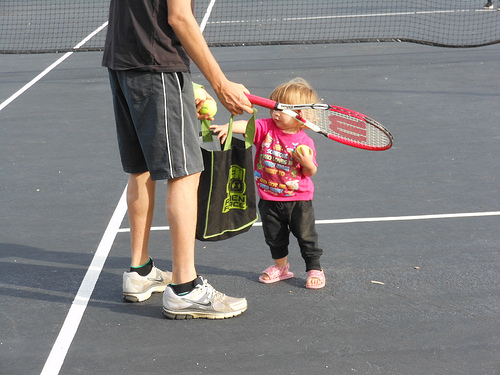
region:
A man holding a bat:
[210, 46, 402, 161]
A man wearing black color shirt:
[90, 0, 210, 150]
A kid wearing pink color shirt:
[230, 72, 327, 217]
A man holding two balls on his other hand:
[180, 69, 218, 142]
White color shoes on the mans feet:
[104, 240, 247, 350]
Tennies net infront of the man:
[258, 1, 382, 61]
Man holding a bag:
[95, 12, 267, 328]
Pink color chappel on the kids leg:
[260, 260, 326, 290]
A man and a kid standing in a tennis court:
[38, 2, 468, 369]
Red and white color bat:
[223, 76, 420, 164]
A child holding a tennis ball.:
[209, 74, 329, 291]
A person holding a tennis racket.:
[106, 2, 392, 322]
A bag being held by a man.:
[199, 106, 263, 246]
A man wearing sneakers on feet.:
[100, 3, 257, 323]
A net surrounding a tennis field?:
[7, 5, 489, 59]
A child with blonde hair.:
[209, 77, 321, 291]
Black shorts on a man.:
[109, 69, 209, 181]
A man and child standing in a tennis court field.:
[102, 61, 326, 321]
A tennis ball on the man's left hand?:
[194, 97, 221, 120]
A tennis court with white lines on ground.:
[9, 7, 486, 372]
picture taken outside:
[7, 9, 431, 371]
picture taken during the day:
[18, 22, 489, 373]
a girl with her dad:
[88, 25, 433, 373]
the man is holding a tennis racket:
[227, 78, 295, 116]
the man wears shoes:
[250, 246, 347, 318]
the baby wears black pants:
[267, 209, 325, 247]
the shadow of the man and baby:
[17, 238, 107, 309]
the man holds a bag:
[201, 120, 259, 252]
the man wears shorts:
[101, 68, 228, 222]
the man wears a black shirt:
[97, 8, 187, 68]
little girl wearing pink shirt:
[220, 75, 337, 287]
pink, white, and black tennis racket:
[248, 87, 393, 153]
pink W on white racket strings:
[322, 112, 370, 144]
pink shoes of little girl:
[250, 262, 330, 292]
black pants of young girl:
[250, 201, 320, 266]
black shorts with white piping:
[108, 68, 210, 173]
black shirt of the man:
[98, 1, 195, 71]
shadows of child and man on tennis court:
[7, 237, 257, 314]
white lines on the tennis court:
[0, 14, 496, 374]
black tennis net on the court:
[0, 3, 498, 43]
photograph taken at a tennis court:
[26, 0, 451, 336]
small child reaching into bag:
[242, 70, 330, 287]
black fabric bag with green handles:
[185, 88, 267, 232]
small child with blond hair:
[254, 63, 337, 283]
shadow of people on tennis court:
[3, 222, 274, 319]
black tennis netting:
[22, 0, 474, 58]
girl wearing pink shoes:
[242, 250, 327, 322]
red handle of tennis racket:
[231, 87, 281, 135]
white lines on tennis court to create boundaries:
[39, 46, 498, 372]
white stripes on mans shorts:
[158, 67, 193, 180]